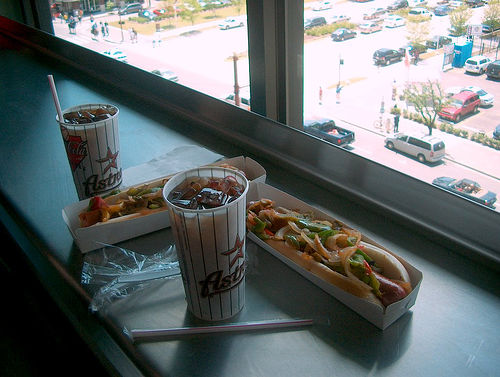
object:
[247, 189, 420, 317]
hot dog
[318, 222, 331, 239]
peppers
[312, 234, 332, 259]
onions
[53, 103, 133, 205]
cup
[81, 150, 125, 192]
logo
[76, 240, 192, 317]
plastic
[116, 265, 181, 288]
utensil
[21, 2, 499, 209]
window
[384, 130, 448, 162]
van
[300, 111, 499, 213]
street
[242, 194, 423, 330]
holder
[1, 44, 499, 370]
counter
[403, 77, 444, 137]
tree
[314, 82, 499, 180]
sidewalk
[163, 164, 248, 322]
cups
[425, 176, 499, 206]
cars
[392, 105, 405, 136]
people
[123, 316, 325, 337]
straw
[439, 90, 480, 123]
suv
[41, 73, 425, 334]
snacks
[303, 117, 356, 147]
truck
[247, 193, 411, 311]
bun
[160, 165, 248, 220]
soda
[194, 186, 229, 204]
ice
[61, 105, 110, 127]
soda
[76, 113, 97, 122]
ice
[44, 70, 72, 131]
straw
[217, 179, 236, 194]
ice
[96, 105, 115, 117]
ice